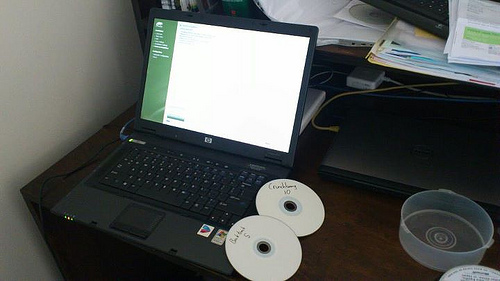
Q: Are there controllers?
A: No, there are no controllers.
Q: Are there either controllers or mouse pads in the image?
A: No, there are no controllers or mouse pads.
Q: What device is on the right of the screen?
A: The device is a router.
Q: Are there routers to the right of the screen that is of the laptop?
A: Yes, there is a router to the right of the screen.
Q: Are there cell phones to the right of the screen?
A: No, there is a router to the right of the screen.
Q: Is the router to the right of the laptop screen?
A: Yes, the router is to the right of the screen.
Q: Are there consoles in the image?
A: No, there are no consoles.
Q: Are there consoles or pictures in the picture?
A: No, there are no consoles or pictures.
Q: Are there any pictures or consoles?
A: No, there are no consoles or pictures.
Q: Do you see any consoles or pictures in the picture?
A: No, there are no consoles or pictures.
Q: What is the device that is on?
A: The device is a screen.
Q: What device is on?
A: The device is a screen.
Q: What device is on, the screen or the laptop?
A: The screen is on.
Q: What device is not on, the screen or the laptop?
A: The laptop is not on.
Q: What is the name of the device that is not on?
A: The device is a laptop.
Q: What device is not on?
A: The device is a laptop.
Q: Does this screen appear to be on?
A: Yes, the screen is on.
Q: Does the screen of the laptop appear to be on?
A: Yes, the screen is on.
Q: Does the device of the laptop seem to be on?
A: Yes, the screen is on.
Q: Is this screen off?
A: No, the screen is on.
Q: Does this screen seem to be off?
A: No, the screen is on.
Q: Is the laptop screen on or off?
A: The screen is on.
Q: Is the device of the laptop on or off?
A: The screen is on.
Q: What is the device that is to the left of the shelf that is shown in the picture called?
A: The device is a screen.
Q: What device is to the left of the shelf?
A: The device is a screen.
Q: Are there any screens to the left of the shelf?
A: Yes, there is a screen to the left of the shelf.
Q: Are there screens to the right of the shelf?
A: No, the screen is to the left of the shelf.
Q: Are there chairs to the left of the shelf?
A: No, there is a screen to the left of the shelf.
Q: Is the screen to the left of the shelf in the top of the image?
A: Yes, the screen is to the left of the shelf.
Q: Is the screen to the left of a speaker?
A: No, the screen is to the left of the shelf.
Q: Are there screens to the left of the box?
A: Yes, there is a screen to the left of the box.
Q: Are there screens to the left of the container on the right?
A: Yes, there is a screen to the left of the box.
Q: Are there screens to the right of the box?
A: No, the screen is to the left of the box.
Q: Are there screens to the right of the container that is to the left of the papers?
A: No, the screen is to the left of the box.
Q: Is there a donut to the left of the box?
A: No, there is a screen to the left of the box.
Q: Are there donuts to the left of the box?
A: No, there is a screen to the left of the box.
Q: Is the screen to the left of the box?
A: Yes, the screen is to the left of the box.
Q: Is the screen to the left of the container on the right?
A: Yes, the screen is to the left of the box.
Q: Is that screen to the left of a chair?
A: No, the screen is to the left of the box.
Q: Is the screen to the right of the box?
A: No, the screen is to the left of the box.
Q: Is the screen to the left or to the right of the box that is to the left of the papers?
A: The screen is to the left of the box.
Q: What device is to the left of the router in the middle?
A: The device is a screen.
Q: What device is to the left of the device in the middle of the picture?
A: The device is a screen.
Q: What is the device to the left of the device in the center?
A: The device is a screen.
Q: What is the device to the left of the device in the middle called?
A: The device is a screen.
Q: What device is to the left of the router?
A: The device is a screen.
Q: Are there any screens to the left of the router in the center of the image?
A: Yes, there is a screen to the left of the router.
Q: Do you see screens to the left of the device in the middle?
A: Yes, there is a screen to the left of the router.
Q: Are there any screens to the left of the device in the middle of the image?
A: Yes, there is a screen to the left of the router.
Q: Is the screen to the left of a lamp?
A: No, the screen is to the left of a router.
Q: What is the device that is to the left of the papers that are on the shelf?
A: The device is a screen.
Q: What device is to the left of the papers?
A: The device is a screen.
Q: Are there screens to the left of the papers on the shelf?
A: Yes, there is a screen to the left of the papers.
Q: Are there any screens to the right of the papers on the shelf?
A: No, the screen is to the left of the papers.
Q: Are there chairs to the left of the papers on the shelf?
A: No, there is a screen to the left of the papers.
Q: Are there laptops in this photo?
A: Yes, there is a laptop.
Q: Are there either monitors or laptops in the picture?
A: Yes, there is a laptop.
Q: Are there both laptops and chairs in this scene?
A: No, there is a laptop but no chairs.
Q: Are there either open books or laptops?
A: Yes, there is an open laptop.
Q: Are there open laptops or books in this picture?
A: Yes, there is an open laptop.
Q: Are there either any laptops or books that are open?
A: Yes, the laptop is open.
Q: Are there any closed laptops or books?
A: Yes, there is a closed laptop.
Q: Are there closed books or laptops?
A: Yes, there is a closed laptop.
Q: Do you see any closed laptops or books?
A: Yes, there is a closed laptop.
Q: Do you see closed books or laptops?
A: Yes, there is a closed laptop.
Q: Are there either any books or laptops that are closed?
A: Yes, the laptop is closed.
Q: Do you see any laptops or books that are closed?
A: Yes, the laptop is closed.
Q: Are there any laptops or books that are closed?
A: Yes, the laptop is closed.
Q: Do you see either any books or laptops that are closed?
A: Yes, the laptop is closed.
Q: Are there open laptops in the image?
A: Yes, there is an open laptop.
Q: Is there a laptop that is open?
A: Yes, there is a laptop that is open.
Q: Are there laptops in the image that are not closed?
A: Yes, there is a open laptop.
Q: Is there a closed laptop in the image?
A: Yes, there is a closed laptop.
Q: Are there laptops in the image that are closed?
A: Yes, there is a closed laptop.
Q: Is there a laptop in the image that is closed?
A: Yes, there is a laptop that is closed.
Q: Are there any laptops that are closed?
A: Yes, there is a laptop that is closed.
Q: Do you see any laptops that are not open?
A: Yes, there is an closed laptop.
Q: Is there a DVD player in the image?
A: No, there are no DVD players.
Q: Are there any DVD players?
A: No, there are no DVD players.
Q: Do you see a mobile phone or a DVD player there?
A: No, there are no DVD players or cell phones.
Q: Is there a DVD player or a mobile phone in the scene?
A: No, there are no DVD players or cell phones.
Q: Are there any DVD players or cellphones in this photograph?
A: No, there are no DVD players or cellphones.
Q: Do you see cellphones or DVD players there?
A: No, there are no DVD players or cellphones.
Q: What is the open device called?
A: The device is a laptop.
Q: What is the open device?
A: The device is a laptop.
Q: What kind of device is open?
A: The device is a laptop.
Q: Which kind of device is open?
A: The device is a laptop.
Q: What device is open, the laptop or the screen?
A: The laptop is open.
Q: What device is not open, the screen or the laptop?
A: The screen is not open.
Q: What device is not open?
A: The device is a screen.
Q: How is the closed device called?
A: The device is a laptop.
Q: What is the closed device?
A: The device is a laptop.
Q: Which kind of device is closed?
A: The device is a laptop.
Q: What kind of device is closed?
A: The device is a laptop.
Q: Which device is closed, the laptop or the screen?
A: The laptop is closed.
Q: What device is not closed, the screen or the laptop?
A: The screen is not closed.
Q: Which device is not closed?
A: The device is a screen.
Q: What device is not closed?
A: The device is a screen.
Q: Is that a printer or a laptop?
A: That is a laptop.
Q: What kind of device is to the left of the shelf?
A: The device is a laptop.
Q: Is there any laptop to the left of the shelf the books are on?
A: Yes, there is a laptop to the left of the shelf.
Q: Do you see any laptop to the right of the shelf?
A: No, the laptop is to the left of the shelf.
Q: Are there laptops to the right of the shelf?
A: No, the laptop is to the left of the shelf.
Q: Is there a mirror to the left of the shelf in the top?
A: No, there is a laptop to the left of the shelf.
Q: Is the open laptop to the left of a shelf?
A: Yes, the laptop is to the left of a shelf.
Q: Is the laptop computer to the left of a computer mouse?
A: No, the laptop computer is to the left of a shelf.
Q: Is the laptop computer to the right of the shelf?
A: No, the laptop computer is to the left of the shelf.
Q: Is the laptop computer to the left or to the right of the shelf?
A: The laptop computer is to the left of the shelf.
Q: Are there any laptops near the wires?
A: Yes, there is a laptop near the wires.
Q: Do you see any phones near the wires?
A: No, there is a laptop near the wires.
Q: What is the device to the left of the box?
A: The device is a laptop.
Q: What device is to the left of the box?
A: The device is a laptop.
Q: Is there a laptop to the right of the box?
A: No, the laptop is to the left of the box.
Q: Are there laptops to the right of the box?
A: No, the laptop is to the left of the box.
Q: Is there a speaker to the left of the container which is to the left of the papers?
A: No, there is a laptop to the left of the box.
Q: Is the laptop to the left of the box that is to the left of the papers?
A: Yes, the laptop is to the left of the box.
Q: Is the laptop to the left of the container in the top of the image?
A: Yes, the laptop is to the left of the box.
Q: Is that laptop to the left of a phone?
A: No, the laptop is to the left of the box.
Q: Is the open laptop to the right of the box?
A: No, the laptop is to the left of the box.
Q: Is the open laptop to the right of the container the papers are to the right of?
A: No, the laptop is to the left of the box.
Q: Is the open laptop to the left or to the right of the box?
A: The laptop is to the left of the box.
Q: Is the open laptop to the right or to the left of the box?
A: The laptop is to the left of the box.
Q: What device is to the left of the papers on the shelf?
A: The device is a laptop.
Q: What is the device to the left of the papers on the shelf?
A: The device is a laptop.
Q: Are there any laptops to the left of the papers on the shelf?
A: Yes, there is a laptop to the left of the papers.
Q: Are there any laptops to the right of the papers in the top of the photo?
A: No, the laptop is to the left of the papers.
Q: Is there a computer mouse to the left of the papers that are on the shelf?
A: No, there is a laptop to the left of the papers.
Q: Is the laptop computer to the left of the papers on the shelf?
A: Yes, the laptop computer is to the left of the papers.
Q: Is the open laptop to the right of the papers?
A: No, the laptop computer is to the left of the papers.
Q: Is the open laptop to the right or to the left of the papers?
A: The laptop computer is to the left of the papers.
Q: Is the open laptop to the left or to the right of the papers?
A: The laptop computer is to the left of the papers.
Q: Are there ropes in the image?
A: No, there are no ropes.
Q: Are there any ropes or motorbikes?
A: No, there are no ropes or motorbikes.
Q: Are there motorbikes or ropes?
A: No, there are no ropes or motorbikes.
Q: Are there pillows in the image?
A: No, there are no pillows.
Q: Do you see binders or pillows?
A: No, there are no pillows or binders.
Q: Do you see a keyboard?
A: Yes, there is a keyboard.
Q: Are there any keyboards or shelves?
A: Yes, there is a keyboard.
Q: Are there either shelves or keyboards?
A: Yes, there is a keyboard.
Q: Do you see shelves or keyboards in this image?
A: Yes, there is a keyboard.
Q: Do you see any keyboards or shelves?
A: Yes, there is a keyboard.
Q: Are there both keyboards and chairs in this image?
A: No, there is a keyboard but no chairs.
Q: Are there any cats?
A: No, there are no cats.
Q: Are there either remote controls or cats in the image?
A: No, there are no cats or remote controls.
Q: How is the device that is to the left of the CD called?
A: The device is a keyboard.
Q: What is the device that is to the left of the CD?
A: The device is a keyboard.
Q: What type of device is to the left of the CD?
A: The device is a keyboard.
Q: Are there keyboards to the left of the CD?
A: Yes, there is a keyboard to the left of the CD.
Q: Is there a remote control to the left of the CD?
A: No, there is a keyboard to the left of the CD.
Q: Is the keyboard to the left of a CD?
A: Yes, the keyboard is to the left of a CD.